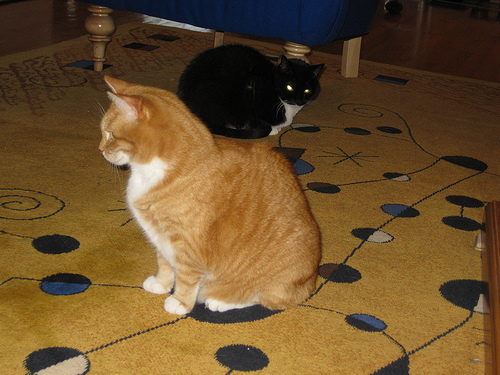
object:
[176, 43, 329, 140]
cat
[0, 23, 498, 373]
floor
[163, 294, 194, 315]
paws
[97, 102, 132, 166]
face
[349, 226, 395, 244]
design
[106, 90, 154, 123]
ear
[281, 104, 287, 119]
whiskers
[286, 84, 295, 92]
eyes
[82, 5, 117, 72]
legs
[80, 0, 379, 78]
table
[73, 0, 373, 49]
tablecloth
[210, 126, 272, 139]
tail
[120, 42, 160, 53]
spots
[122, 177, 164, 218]
chest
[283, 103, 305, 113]
neck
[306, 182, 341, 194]
circle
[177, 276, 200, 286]
stripes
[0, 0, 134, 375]
left